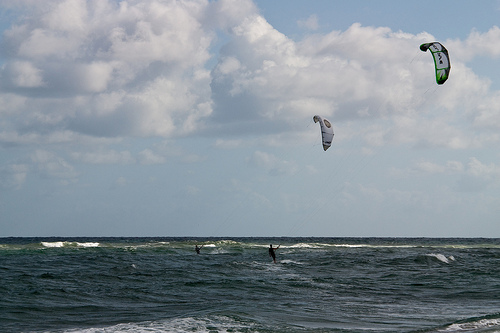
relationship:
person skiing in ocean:
[268, 244, 281, 265] [0, 237, 497, 330]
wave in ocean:
[1, 231, 498, 263] [0, 237, 497, 330]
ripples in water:
[73, 261, 211, 309] [73, 249, 150, 290]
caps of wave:
[42, 237, 98, 248] [32, 240, 489, 250]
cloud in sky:
[10, 155, 30, 189] [5, 1, 495, 236]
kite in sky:
[281, 80, 386, 168] [5, 1, 495, 236]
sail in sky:
[421, 41, 452, 83] [5, 1, 495, 236]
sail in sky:
[419, 42, 450, 86] [348, 66, 413, 133]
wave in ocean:
[211, 262, 443, 293] [30, 187, 490, 322]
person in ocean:
[268, 244, 281, 265] [0, 236, 500, 333]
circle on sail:
[321, 109, 333, 132] [301, 100, 340, 157]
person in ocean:
[264, 239, 281, 265] [0, 236, 500, 333]